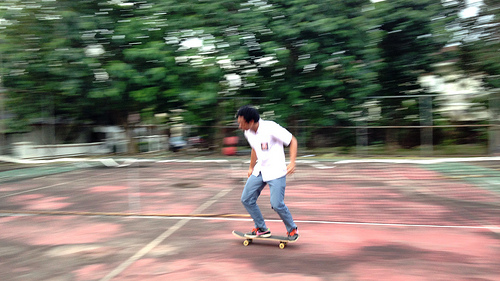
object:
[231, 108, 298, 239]
man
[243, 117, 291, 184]
shirt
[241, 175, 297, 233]
pants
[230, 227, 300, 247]
skateboard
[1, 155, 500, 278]
tennis court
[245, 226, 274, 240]
shoe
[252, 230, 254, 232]
laces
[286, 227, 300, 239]
shoe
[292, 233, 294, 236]
laces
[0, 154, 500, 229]
tennis net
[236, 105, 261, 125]
hair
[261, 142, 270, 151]
logo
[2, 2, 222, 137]
tree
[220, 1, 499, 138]
tree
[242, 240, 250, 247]
wheel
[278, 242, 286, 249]
wheel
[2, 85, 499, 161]
wire fence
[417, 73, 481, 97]
sky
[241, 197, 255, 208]
knee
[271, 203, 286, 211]
knee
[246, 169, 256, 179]
hand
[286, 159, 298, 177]
hand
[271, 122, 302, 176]
arm